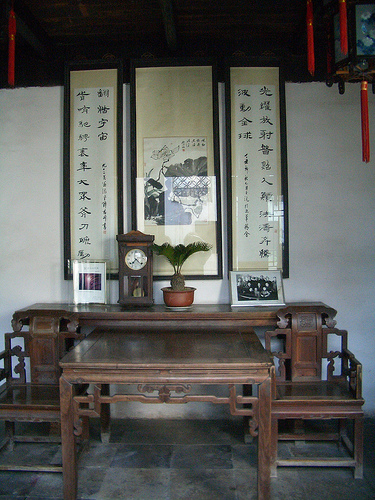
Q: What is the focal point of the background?
A: Picture in a frame on a wall.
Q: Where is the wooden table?
A: In front of the desk and photos.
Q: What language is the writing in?
A: Chinese.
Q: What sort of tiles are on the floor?
A: Stone.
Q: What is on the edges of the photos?
A: Black frame.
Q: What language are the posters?
A: Japanese.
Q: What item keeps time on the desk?
A: Clock.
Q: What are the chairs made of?
A: Wood.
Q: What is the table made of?
A: Wood.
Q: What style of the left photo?
A: Black and white.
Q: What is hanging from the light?
A: Tassel.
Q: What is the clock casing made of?
A: Wood.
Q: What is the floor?
A: Tile.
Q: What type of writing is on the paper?
A: Calligraphy.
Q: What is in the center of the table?
A: Plant.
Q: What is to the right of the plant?
A: Photo.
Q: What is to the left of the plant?
A: Clock.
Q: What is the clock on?
A: Desk.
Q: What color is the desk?
A: Brown.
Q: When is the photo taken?
A: Daytime.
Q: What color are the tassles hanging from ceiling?
A: Red.